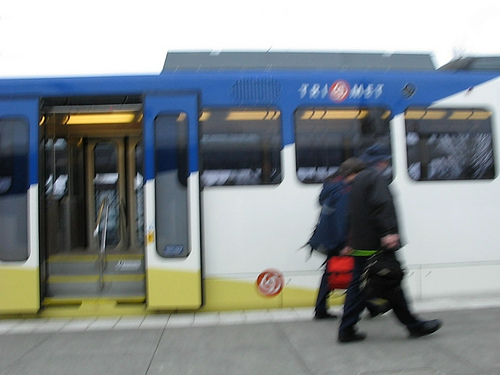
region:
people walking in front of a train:
[4, 22, 499, 359]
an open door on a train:
[13, 84, 198, 331]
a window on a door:
[150, 102, 192, 265]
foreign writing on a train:
[301, 79, 387, 106]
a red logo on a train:
[252, 268, 287, 302]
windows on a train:
[199, 93, 499, 180]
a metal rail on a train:
[90, 193, 112, 289]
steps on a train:
[52, 253, 141, 318]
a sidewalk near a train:
[51, 309, 498, 373]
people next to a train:
[305, 128, 468, 366]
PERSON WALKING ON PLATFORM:
[331, 136, 446, 351]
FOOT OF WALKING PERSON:
[336, 329, 378, 345]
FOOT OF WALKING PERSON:
[401, 317, 448, 343]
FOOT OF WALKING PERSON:
[311, 305, 343, 325]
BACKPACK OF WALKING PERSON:
[338, 250, 413, 307]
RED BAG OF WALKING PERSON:
[324, 256, 354, 286]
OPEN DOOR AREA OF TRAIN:
[28, 96, 149, 313]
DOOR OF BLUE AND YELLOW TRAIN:
[134, 84, 207, 312]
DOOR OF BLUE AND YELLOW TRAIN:
[1, 95, 51, 319]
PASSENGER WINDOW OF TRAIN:
[400, 109, 499, 188]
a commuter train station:
[5, 26, 497, 316]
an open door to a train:
[24, 85, 202, 307]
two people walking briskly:
[280, 121, 452, 348]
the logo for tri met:
[292, 74, 414, 116]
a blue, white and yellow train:
[37, 43, 312, 343]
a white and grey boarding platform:
[50, 310, 188, 367]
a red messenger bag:
[322, 250, 357, 289]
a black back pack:
[350, 238, 415, 320]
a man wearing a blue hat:
[355, 133, 422, 220]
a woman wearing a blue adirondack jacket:
[304, 178, 351, 251]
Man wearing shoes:
[335, 315, 447, 347]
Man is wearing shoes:
[337, 312, 446, 345]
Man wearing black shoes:
[332, 316, 447, 342]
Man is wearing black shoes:
[336, 315, 446, 345]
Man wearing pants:
[335, 248, 420, 330]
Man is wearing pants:
[340, 251, 425, 333]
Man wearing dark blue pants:
[337, 247, 423, 333]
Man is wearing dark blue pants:
[333, 249, 428, 331]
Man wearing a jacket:
[342, 164, 402, 251]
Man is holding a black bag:
[355, 242, 409, 314]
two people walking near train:
[307, 142, 445, 347]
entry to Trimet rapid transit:
[15, 80, 200, 311]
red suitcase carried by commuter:
[325, 245, 356, 291]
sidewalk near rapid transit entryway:
[1, 317, 303, 373]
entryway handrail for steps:
[90, 192, 115, 298]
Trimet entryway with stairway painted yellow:
[53, 256, 140, 298]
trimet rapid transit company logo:
[296, 68, 391, 104]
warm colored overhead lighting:
[53, 103, 493, 124]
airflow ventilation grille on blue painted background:
[231, 71, 289, 102]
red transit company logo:
[252, 268, 292, 303]